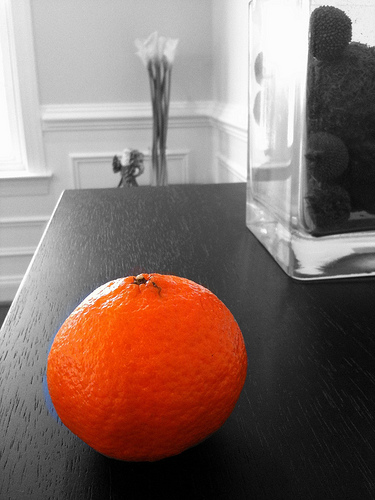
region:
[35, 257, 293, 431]
the orange is in color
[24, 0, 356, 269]
the picture is black and white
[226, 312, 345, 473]
the table is black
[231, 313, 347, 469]
the table is made of wood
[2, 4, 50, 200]
the window is white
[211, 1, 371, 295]
the glass vase is square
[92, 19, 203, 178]
the flowers are white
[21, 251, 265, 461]
the orange looks juicy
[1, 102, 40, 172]
the sun is coming through the window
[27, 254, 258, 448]
the orange is bumpy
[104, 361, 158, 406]
dark bumpy orange texture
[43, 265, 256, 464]
oval shaped fruit commonly called an orange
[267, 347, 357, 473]
dark shadows on wood grained desk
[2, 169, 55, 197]
smooth white wooden window sill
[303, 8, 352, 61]
dead grey flower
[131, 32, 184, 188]
white flowers on long stems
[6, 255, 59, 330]
light reflecting off wooden desk top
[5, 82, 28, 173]
flimsy white curtains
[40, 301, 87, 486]
blue half circle bordering orange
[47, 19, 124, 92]
greyish white wallpaper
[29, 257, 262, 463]
The orange is on the counter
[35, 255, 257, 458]
The fruit is orange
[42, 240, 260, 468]
The fruit is round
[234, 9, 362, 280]
A tall glass jar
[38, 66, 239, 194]
White panels on bottom of wall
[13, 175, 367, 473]
Counter with grain pattern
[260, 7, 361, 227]
Round prickly balls in jar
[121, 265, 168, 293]
Brown end of orange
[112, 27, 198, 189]
Decorations next to wall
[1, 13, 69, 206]
Window on other side of table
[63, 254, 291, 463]
orange on a table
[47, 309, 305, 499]
orange is the only color in the picture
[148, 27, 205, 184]
white flowers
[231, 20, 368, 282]
clear vase on the table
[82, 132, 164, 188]
statue next to flowers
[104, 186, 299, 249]
table is made of wood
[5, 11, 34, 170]
light coming in from window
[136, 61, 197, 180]
flowers have long stems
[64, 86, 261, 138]
door railing trim on the wall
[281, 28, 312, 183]
reflection on the vase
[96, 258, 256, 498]
an orange fruit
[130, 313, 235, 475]
an orange fruit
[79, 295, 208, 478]
an orange fruit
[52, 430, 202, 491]
an orange fruit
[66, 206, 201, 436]
an orange fruit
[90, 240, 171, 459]
an orange fruit